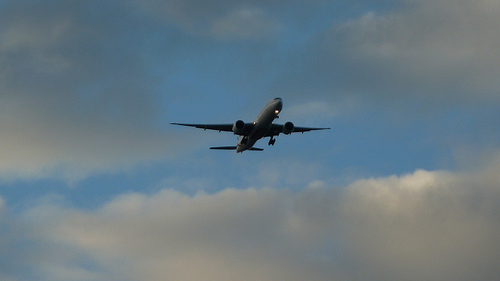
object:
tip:
[269, 98, 283, 106]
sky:
[0, 0, 499, 281]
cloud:
[334, 151, 500, 281]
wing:
[168, 122, 249, 134]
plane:
[166, 97, 332, 152]